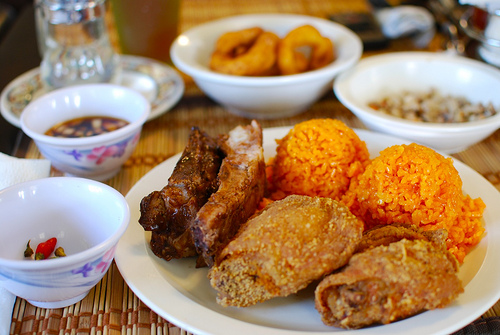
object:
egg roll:
[312, 228, 465, 333]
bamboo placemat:
[6, 273, 182, 334]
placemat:
[8, 91, 500, 334]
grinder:
[34, 0, 124, 92]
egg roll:
[212, 198, 367, 300]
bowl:
[334, 47, 499, 153]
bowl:
[170, 10, 362, 118]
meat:
[144, 115, 244, 272]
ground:
[441, 147, 455, 162]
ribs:
[131, 108, 273, 253]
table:
[0, 10, 497, 335]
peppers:
[4, 209, 90, 271]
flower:
[67, 260, 98, 282]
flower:
[92, 246, 120, 278]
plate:
[114, 120, 499, 334]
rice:
[259, 114, 489, 320]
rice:
[256, 112, 487, 272]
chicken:
[221, 176, 459, 320]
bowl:
[1, 175, 131, 309]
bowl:
[19, 83, 150, 180]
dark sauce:
[43, 108, 130, 137]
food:
[0, 3, 498, 324]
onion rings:
[209, 22, 336, 74]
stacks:
[267, 108, 479, 235]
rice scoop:
[347, 143, 486, 247]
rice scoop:
[262, 119, 362, 200]